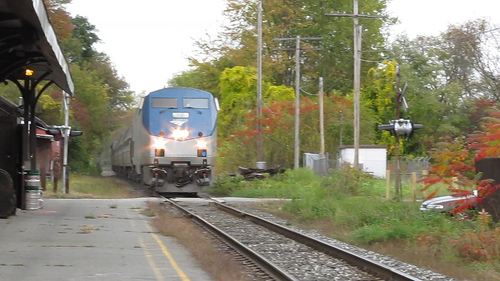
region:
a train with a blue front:
[104, 87, 222, 194]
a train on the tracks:
[97, 84, 414, 280]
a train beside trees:
[105, 66, 350, 194]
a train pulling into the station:
[5, 0, 275, 278]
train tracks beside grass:
[190, 198, 417, 280]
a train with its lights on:
[106, 91, 225, 191]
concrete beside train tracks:
[77, 189, 297, 276]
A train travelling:
[105, 84, 220, 199]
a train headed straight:
[99, 84, 229, 196]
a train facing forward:
[93, 91, 218, 195]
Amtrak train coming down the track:
[107, 86, 219, 191]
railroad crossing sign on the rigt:
[377, 80, 423, 192]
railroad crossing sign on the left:
[45, 97, 79, 197]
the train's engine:
[132, 85, 217, 192]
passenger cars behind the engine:
[108, 123, 136, 184]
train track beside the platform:
[167, 195, 421, 280]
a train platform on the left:
[5, 3, 198, 279]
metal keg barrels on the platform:
[24, 169, 41, 210]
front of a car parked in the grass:
[421, 190, 481, 217]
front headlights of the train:
[155, 128, 207, 147]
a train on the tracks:
[94, 88, 224, 194]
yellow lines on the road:
[121, 188, 193, 280]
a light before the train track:
[370, 70, 426, 200]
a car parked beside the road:
[413, 179, 486, 221]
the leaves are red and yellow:
[423, 98, 498, 203]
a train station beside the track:
[0, 0, 88, 215]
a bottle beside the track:
[20, 161, 46, 215]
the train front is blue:
[139, 84, 216, 139]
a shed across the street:
[334, 134, 390, 182]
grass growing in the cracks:
[76, 212, 157, 222]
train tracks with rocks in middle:
[166, 179, 421, 279]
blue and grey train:
[110, 62, 238, 190]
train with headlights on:
[117, 73, 258, 203]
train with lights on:
[122, 82, 264, 187]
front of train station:
[6, 0, 100, 262]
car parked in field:
[408, 160, 499, 240]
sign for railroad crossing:
[368, 45, 431, 215]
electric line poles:
[253, 8, 406, 168]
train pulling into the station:
[97, 61, 265, 248]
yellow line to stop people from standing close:
[113, 188, 183, 274]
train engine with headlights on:
[130, 76, 225, 197]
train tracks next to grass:
[173, 193, 373, 279]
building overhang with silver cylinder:
[8, 0, 85, 232]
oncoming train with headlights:
[95, 82, 223, 203]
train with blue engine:
[103, 75, 222, 202]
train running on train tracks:
[101, 80, 251, 237]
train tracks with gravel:
[168, 188, 314, 279]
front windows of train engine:
[141, 82, 225, 125]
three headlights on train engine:
[150, 122, 215, 163]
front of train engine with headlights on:
[139, 82, 225, 192]